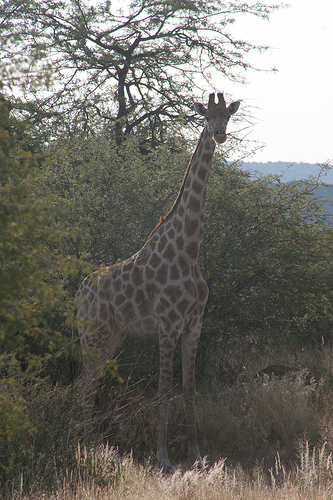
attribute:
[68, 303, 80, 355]
tail — thin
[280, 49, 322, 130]
clouds — white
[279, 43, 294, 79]
clouds — white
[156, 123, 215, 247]
neck — elongated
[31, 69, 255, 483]
giraffe — white, brown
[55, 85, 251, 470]
giraffe — tall, brown, white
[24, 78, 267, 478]
giraffe — brown, white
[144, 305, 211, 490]
legs — frontal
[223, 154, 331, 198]
land — distant, gray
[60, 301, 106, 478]
legs — back legs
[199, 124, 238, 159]
giraffe nostrils — black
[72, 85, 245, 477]
giraffe — big, adult